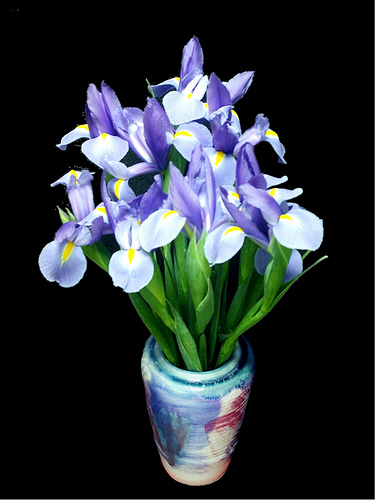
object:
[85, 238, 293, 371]
stems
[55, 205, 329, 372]
flowerstems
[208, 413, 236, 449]
plum color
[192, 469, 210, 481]
pink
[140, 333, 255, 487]
vase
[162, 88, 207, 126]
heart petal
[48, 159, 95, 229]
shirt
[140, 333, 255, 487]
jar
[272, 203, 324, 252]
iris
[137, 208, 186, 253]
iris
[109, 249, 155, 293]
iris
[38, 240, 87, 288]
iris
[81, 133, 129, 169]
iris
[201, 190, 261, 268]
flower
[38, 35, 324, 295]
flower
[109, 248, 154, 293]
petal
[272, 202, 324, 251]
petal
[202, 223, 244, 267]
petal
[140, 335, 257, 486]
pot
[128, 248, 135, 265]
center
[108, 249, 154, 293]
flower